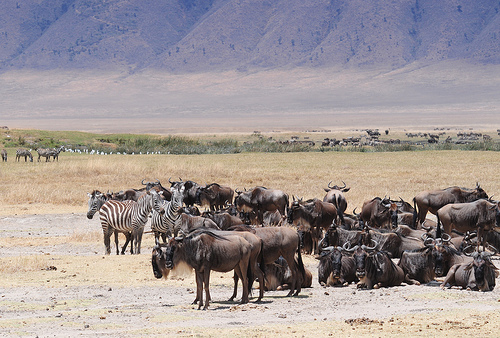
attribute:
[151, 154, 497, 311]
wildebeest — open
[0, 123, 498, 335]
field — open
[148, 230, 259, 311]
animal — herd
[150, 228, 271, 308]
animal — brown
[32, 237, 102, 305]
ground — dirt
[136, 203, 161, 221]
stripes — black, white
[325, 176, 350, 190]
horns — curved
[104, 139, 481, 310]
animals — laying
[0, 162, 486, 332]
field — open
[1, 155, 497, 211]
grass — yellow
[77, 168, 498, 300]
animals — female, male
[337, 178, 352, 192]
horn — sharp